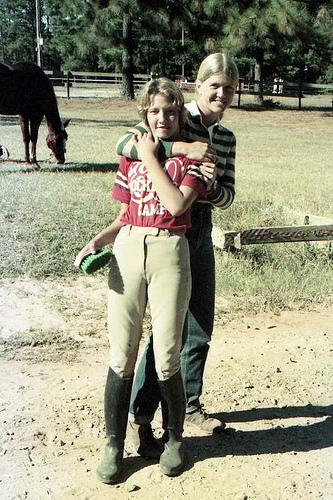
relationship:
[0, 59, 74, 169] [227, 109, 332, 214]
horse on field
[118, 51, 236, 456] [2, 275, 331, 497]
girl on dirt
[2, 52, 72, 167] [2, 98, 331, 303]
horse eats grass